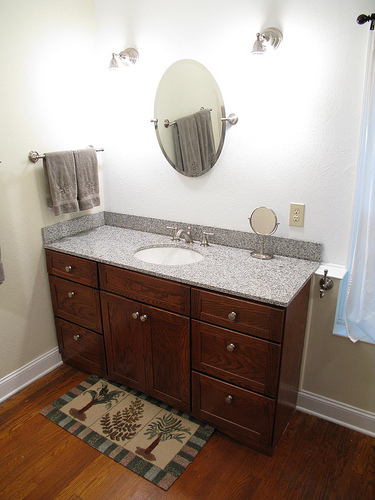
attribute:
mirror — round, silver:
[247, 204, 279, 259]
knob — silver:
[61, 262, 73, 274]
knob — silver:
[66, 290, 77, 301]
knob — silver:
[72, 332, 82, 343]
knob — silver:
[129, 308, 141, 322]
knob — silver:
[137, 313, 149, 323]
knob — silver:
[225, 309, 241, 323]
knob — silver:
[224, 342, 238, 354]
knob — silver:
[223, 391, 236, 407]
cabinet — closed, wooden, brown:
[42, 249, 287, 461]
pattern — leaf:
[62, 381, 198, 470]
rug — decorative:
[38, 371, 220, 493]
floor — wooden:
[1, 363, 374, 498]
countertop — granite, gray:
[42, 212, 322, 308]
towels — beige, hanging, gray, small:
[41, 147, 102, 212]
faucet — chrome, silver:
[173, 228, 194, 248]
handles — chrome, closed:
[165, 224, 216, 247]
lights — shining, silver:
[101, 24, 287, 75]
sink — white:
[131, 242, 208, 271]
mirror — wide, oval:
[146, 55, 240, 180]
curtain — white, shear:
[331, 29, 373, 346]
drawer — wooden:
[188, 369, 278, 451]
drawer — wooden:
[189, 319, 284, 401]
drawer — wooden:
[196, 288, 287, 343]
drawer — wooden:
[53, 315, 106, 377]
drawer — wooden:
[49, 276, 104, 334]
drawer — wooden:
[40, 246, 100, 290]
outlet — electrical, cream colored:
[289, 202, 307, 230]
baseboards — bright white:
[1, 342, 374, 439]